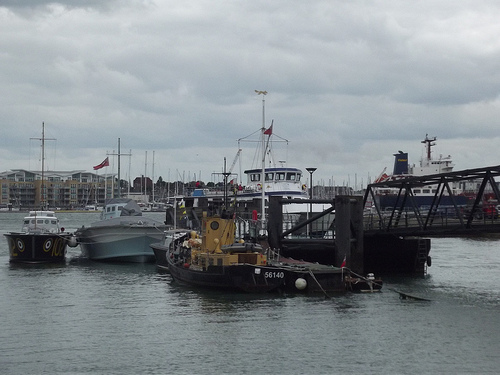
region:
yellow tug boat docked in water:
[165, 175, 272, 307]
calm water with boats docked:
[1, 209, 499, 365]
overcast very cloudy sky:
[28, 13, 493, 175]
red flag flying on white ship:
[86, 153, 118, 171]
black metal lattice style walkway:
[368, 162, 498, 242]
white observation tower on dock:
[241, 160, 308, 197]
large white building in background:
[8, 161, 132, 207]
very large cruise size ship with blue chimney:
[370, 131, 495, 213]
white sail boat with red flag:
[77, 150, 162, 266]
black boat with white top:
[1, 201, 71, 271]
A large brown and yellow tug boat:
[163, 220, 348, 310]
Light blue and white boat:
[72, 219, 169, 278]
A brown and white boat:
[3, 204, 78, 270]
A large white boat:
[252, 163, 329, 227]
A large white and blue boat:
[371, 124, 498, 210]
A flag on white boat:
[256, 114, 283, 141]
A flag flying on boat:
[89, 152, 111, 176]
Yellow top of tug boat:
[185, 213, 259, 270]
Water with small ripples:
[60, 281, 181, 356]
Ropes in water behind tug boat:
[307, 268, 424, 335]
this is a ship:
[153, 185, 360, 314]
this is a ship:
[82, 185, 172, 288]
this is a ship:
[0, 186, 74, 266]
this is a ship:
[362, 195, 437, 295]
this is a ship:
[239, 148, 334, 225]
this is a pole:
[27, 122, 73, 227]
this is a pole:
[97, 133, 132, 203]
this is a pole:
[137, 139, 167, 219]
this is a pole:
[234, 49, 292, 219]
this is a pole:
[415, 128, 464, 245]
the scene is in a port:
[43, 79, 454, 371]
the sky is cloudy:
[14, 53, 239, 115]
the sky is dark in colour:
[49, 74, 181, 92]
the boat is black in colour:
[9, 189, 82, 284]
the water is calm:
[45, 321, 200, 373]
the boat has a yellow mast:
[171, 157, 252, 281]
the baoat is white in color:
[223, 146, 319, 200]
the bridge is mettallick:
[370, 115, 498, 290]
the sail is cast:
[63, 152, 135, 185]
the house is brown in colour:
[0, 149, 122, 205]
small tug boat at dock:
[166, 157, 342, 293]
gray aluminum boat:
[77, 137, 169, 266]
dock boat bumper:
[294, 271, 307, 290]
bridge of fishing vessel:
[244, 167, 303, 193]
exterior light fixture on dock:
[305, 166, 317, 235]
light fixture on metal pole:
[305, 168, 315, 234]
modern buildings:
[1, 169, 129, 209]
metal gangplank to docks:
[357, 180, 412, 238]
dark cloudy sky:
[0, 0, 497, 178]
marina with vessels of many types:
[5, 125, 497, 299]